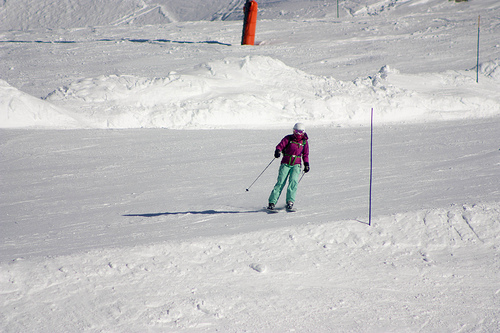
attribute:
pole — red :
[241, 0, 257, 45]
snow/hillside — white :
[16, 3, 202, 50]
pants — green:
[267, 162, 303, 202]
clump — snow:
[205, 65, 335, 114]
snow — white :
[0, 214, 500, 328]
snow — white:
[150, 287, 237, 327]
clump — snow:
[105, 260, 118, 272]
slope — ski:
[6, 197, 499, 328]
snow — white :
[342, 221, 412, 287]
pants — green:
[267, 159, 304, 213]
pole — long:
[367, 102, 376, 224]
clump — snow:
[247, 259, 274, 273]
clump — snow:
[105, 260, 115, 268]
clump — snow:
[215, 241, 224, 251]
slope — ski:
[13, 32, 497, 326]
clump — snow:
[391, 192, 491, 258]